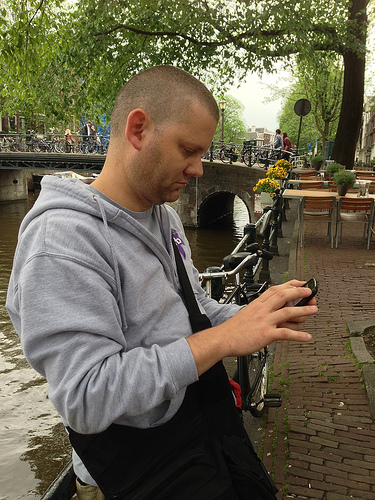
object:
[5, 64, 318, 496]
man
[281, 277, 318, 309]
phone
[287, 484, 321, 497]
brick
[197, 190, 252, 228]
arch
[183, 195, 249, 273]
water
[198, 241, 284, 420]
bike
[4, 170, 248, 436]
sweatshirt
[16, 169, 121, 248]
hood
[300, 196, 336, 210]
back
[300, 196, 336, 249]
chair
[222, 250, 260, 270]
seat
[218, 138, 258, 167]
bike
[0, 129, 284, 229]
bridge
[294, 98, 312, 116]
sign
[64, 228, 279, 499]
bag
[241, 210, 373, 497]
walkway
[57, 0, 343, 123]
branch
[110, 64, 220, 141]
hair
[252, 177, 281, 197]
flower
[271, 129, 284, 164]
person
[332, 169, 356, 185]
plant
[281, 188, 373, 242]
table